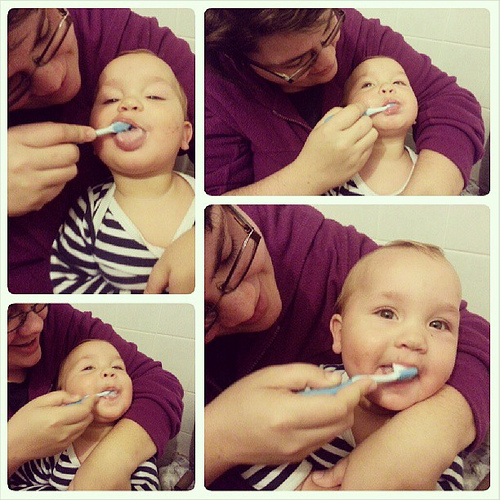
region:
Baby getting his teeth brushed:
[288, 235, 476, 481]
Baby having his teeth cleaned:
[271, 225, 472, 491]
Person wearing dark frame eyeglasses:
[203, 213, 294, 351]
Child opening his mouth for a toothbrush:
[85, 50, 190, 220]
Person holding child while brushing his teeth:
[15, 320, 181, 480]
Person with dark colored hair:
[198, 7, 341, 87]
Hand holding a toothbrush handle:
[257, 360, 378, 462]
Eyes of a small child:
[366, 291, 457, 336]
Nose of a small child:
[395, 326, 431, 356]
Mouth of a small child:
[105, 113, 150, 155]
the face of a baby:
[87, 48, 189, 180]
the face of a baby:
[343, 55, 427, 136]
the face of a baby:
[59, 338, 133, 423]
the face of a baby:
[330, 237, 464, 413]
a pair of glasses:
[8, 9, 74, 106]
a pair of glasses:
[243, 9, 347, 83]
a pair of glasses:
[9, 302, 49, 334]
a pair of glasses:
[207, 209, 261, 335]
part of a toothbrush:
[98, 123, 145, 148]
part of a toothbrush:
[93, 390, 123, 401]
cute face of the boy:
[96, 60, 176, 176]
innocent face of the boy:
[334, 259, 471, 424]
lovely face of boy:
[340, 62, 423, 167]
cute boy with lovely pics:
[21, 22, 475, 474]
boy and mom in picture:
[26, 22, 477, 475]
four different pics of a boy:
[26, 34, 486, 364]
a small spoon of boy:
[96, 117, 130, 147]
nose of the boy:
[397, 337, 428, 357]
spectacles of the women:
[271, 15, 356, 99]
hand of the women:
[12, 117, 74, 229]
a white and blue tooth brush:
[96, 119, 129, 136]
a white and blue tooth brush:
[360, 99, 394, 115]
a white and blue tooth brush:
[306, 361, 421, 398]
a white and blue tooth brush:
[74, 386, 116, 403]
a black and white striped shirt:
[47, 172, 197, 294]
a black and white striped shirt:
[314, 139, 416, 196]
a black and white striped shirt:
[18, 432, 158, 487]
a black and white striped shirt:
[249, 404, 468, 489]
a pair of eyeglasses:
[250, 8, 344, 90]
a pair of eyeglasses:
[10, 9, 73, 110]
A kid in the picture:
[47, 38, 197, 293]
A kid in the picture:
[51, 327, 165, 492]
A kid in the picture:
[309, 237, 476, 496]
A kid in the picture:
[337, 42, 475, 202]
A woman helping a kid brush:
[9, 8, 197, 290]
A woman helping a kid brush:
[5, 301, 195, 490]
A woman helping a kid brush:
[205, 202, 490, 488]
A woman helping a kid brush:
[202, 8, 495, 195]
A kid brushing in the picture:
[10, 10, 196, 302]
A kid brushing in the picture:
[202, 202, 498, 495]